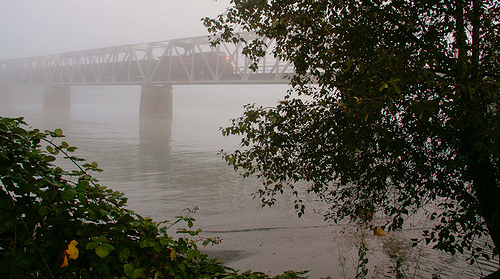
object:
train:
[1, 50, 237, 84]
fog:
[0, 3, 248, 119]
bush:
[3, 117, 228, 277]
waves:
[99, 143, 241, 201]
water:
[19, 116, 359, 239]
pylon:
[136, 83, 172, 156]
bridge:
[0, 28, 285, 143]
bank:
[187, 219, 305, 263]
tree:
[200, 0, 498, 253]